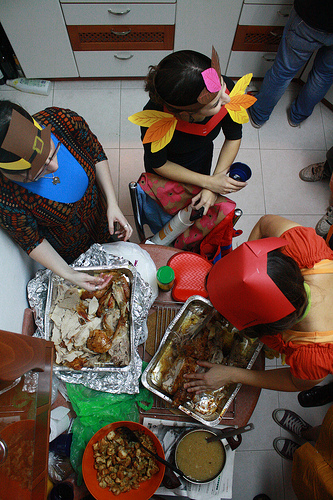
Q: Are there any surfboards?
A: No, there are no surfboards.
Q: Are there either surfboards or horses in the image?
A: No, there are no surfboards or horses.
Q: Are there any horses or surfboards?
A: No, there are no surfboards or horses.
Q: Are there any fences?
A: No, there are no fences.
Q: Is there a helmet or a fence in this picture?
A: No, there are no fences or helmets.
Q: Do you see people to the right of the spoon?
A: Yes, there is a person to the right of the spoon.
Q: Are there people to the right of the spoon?
A: Yes, there is a person to the right of the spoon.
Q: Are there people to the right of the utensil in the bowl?
A: Yes, there is a person to the right of the spoon.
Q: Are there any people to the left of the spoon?
A: No, the person is to the right of the spoon.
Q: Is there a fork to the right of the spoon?
A: No, there is a person to the right of the spoon.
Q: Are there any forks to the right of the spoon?
A: No, there is a person to the right of the spoon.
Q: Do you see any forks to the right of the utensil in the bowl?
A: No, there is a person to the right of the spoon.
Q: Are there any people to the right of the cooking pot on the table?
A: Yes, there is a person to the right of the cooking pot.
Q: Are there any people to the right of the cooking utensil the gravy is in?
A: Yes, there is a person to the right of the cooking pot.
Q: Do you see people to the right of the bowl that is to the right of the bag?
A: Yes, there is a person to the right of the bowl.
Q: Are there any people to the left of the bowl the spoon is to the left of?
A: No, the person is to the right of the bowl.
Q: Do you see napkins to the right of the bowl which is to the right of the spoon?
A: No, there is a person to the right of the bowl.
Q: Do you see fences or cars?
A: No, there are no fences or cars.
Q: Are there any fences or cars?
A: No, there are no fences or cars.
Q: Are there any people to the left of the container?
A: Yes, there is a person to the left of the container.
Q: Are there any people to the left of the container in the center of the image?
A: Yes, there is a person to the left of the container.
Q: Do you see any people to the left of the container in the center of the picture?
A: Yes, there is a person to the left of the container.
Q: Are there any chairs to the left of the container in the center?
A: No, there is a person to the left of the container.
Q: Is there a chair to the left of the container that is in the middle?
A: No, there is a person to the left of the container.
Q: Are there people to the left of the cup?
A: Yes, there is a person to the left of the cup.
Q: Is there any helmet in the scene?
A: No, there are no helmets.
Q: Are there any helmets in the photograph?
A: No, there are no helmets.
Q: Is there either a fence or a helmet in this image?
A: No, there are no helmets or fences.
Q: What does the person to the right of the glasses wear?
A: The person wears a ring.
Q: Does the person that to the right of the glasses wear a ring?
A: Yes, the person wears a ring.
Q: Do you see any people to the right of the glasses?
A: Yes, there is a person to the right of the glasses.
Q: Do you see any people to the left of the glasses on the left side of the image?
A: No, the person is to the right of the glasses.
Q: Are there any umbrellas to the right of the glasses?
A: No, there is a person to the right of the glasses.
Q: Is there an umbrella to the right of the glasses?
A: No, there is a person to the right of the glasses.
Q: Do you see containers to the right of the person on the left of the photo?
A: Yes, there is a container to the right of the person.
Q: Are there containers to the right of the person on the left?
A: Yes, there is a container to the right of the person.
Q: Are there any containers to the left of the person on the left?
A: No, the container is to the right of the person.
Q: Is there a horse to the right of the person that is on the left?
A: No, there is a container to the right of the person.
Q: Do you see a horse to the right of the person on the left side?
A: No, there is a container to the right of the person.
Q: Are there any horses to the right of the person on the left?
A: No, there is a container to the right of the person.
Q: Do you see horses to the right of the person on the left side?
A: No, there is a container to the right of the person.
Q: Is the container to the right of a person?
A: Yes, the container is to the right of a person.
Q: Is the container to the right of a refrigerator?
A: No, the container is to the right of a person.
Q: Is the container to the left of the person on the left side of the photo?
A: No, the container is to the right of the person.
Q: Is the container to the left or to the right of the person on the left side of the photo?
A: The container is to the right of the person.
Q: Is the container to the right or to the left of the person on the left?
A: The container is to the right of the person.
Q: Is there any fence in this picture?
A: No, there are no fences.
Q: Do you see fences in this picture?
A: No, there are no fences.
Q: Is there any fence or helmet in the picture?
A: No, there are no fences or helmets.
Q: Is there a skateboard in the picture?
A: No, there are no skateboards.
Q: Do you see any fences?
A: No, there are no fences.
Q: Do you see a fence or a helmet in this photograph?
A: No, there are no fences or helmets.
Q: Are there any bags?
A: Yes, there is a bag.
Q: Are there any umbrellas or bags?
A: Yes, there is a bag.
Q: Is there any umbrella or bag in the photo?
A: Yes, there is a bag.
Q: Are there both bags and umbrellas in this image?
A: No, there is a bag but no umbrellas.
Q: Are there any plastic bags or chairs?
A: Yes, there is a plastic bag.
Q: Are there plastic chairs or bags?
A: Yes, there is a plastic bag.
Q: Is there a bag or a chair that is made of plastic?
A: Yes, the bag is made of plastic.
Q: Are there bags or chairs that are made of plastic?
A: Yes, the bag is made of plastic.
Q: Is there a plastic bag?
A: Yes, there is a bag that is made of plastic.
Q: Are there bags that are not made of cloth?
A: Yes, there is a bag that is made of plastic.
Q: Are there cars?
A: No, there are no cars.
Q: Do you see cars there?
A: No, there are no cars.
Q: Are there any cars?
A: No, there are no cars.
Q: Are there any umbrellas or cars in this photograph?
A: No, there are no cars or umbrellas.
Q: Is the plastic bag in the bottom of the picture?
A: Yes, the bag is in the bottom of the image.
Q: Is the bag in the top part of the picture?
A: No, the bag is in the bottom of the image.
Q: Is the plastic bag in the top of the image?
A: No, the bag is in the bottom of the image.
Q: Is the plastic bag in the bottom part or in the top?
A: The bag is in the bottom of the image.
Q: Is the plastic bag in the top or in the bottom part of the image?
A: The bag is in the bottom of the image.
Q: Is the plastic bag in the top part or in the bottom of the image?
A: The bag is in the bottom of the image.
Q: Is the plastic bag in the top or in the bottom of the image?
A: The bag is in the bottom of the image.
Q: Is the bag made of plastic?
A: Yes, the bag is made of plastic.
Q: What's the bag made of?
A: The bag is made of plastic.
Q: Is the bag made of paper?
A: No, the bag is made of plastic.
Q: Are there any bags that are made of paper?
A: No, there is a bag but it is made of plastic.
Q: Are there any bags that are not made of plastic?
A: No, there is a bag but it is made of plastic.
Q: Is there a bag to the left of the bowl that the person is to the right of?
A: Yes, there is a bag to the left of the bowl.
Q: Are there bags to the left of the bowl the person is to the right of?
A: Yes, there is a bag to the left of the bowl.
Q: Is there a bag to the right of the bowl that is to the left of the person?
A: No, the bag is to the left of the bowl.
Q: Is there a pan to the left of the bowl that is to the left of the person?
A: No, there is a bag to the left of the bowl.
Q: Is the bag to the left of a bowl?
A: Yes, the bag is to the left of a bowl.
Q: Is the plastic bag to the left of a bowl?
A: Yes, the bag is to the left of a bowl.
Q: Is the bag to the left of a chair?
A: No, the bag is to the left of a bowl.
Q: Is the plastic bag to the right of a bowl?
A: No, the bag is to the left of a bowl.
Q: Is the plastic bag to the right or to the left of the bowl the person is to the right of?
A: The bag is to the left of the bowl.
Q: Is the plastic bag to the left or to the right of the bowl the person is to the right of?
A: The bag is to the left of the bowl.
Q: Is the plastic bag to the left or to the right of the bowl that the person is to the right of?
A: The bag is to the left of the bowl.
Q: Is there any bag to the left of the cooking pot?
A: Yes, there is a bag to the left of the cooking pot.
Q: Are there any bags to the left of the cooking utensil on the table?
A: Yes, there is a bag to the left of the cooking pot.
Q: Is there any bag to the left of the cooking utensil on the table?
A: Yes, there is a bag to the left of the cooking pot.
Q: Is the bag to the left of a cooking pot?
A: Yes, the bag is to the left of a cooking pot.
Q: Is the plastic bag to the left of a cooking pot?
A: Yes, the bag is to the left of a cooking pot.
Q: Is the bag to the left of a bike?
A: No, the bag is to the left of a cooking pot.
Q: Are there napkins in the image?
A: No, there are no napkins.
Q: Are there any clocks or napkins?
A: No, there are no napkins or clocks.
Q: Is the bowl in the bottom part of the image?
A: Yes, the bowl is in the bottom of the image.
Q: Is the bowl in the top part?
A: No, the bowl is in the bottom of the image.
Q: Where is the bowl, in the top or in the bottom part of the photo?
A: The bowl is in the bottom of the image.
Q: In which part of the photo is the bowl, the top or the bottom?
A: The bowl is in the bottom of the image.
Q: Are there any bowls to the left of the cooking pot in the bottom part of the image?
A: Yes, there is a bowl to the left of the cooking pot.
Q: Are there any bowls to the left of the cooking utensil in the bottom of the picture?
A: Yes, there is a bowl to the left of the cooking pot.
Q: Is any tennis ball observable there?
A: No, there are no tennis balls.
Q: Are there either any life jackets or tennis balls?
A: No, there are no tennis balls or life jackets.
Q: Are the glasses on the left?
A: Yes, the glasses are on the left of the image.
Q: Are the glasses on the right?
A: No, the glasses are on the left of the image.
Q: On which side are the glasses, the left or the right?
A: The glasses are on the left of the image.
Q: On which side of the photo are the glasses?
A: The glasses are on the left of the image.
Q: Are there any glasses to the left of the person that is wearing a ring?
A: Yes, there are glasses to the left of the person.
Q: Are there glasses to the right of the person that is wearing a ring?
A: No, the glasses are to the left of the person.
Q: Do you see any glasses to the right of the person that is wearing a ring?
A: No, the glasses are to the left of the person.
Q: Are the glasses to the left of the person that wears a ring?
A: Yes, the glasses are to the left of the person.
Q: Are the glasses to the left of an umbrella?
A: No, the glasses are to the left of the person.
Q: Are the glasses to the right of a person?
A: No, the glasses are to the left of a person.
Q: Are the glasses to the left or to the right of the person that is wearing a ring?
A: The glasses are to the left of the person.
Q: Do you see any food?
A: Yes, there is food.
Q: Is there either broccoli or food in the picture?
A: Yes, there is food.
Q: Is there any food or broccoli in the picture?
A: Yes, there is food.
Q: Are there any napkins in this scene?
A: No, there are no napkins.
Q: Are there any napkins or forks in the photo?
A: No, there are no napkins or forks.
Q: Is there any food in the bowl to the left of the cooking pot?
A: Yes, there is food in the bowl.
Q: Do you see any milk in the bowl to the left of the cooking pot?
A: No, there is food in the bowl.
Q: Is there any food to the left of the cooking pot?
A: Yes, there is food to the left of the cooking pot.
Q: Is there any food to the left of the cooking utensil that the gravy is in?
A: Yes, there is food to the left of the cooking pot.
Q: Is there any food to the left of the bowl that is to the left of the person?
A: Yes, there is food to the left of the bowl.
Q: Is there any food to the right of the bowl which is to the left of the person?
A: No, the food is to the left of the bowl.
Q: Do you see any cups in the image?
A: Yes, there is a cup.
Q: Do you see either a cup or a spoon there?
A: Yes, there is a cup.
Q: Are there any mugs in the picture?
A: No, there are no mugs.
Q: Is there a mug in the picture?
A: No, there are no mugs.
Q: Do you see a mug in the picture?
A: No, there are no mugs.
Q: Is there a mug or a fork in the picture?
A: No, there are no mugs or forks.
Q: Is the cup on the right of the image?
A: Yes, the cup is on the right of the image.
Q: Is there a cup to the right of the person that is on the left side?
A: Yes, there is a cup to the right of the person.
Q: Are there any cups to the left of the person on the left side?
A: No, the cup is to the right of the person.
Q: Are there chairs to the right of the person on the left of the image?
A: No, there is a cup to the right of the person.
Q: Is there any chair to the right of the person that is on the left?
A: No, there is a cup to the right of the person.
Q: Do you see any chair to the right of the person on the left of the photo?
A: No, there is a cup to the right of the person.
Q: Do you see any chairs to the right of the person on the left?
A: No, there is a cup to the right of the person.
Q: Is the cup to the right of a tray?
A: No, the cup is to the right of the person.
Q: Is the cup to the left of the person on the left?
A: No, the cup is to the right of the person.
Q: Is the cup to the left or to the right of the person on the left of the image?
A: The cup is to the right of the person.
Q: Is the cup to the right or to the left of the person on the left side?
A: The cup is to the right of the person.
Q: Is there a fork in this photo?
A: No, there are no forks.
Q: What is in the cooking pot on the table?
A: The gravy is in the cooking pot.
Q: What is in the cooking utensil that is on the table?
A: The gravy is in the cooking pot.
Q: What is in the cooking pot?
A: The gravy is in the cooking pot.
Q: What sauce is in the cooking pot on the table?
A: The sauce is gravy.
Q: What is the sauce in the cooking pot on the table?
A: The sauce is gravy.